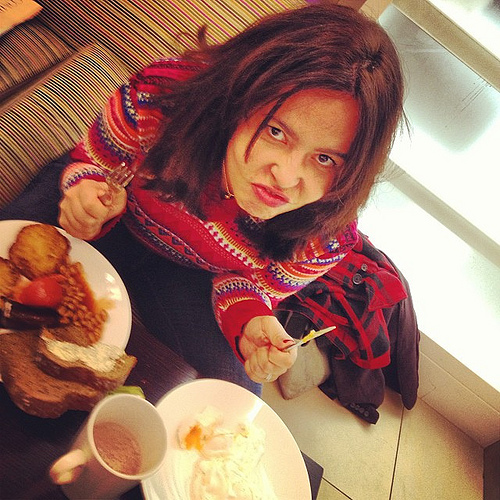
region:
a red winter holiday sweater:
[65, 49, 351, 362]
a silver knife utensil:
[282, 322, 333, 351]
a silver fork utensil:
[98, 160, 133, 206]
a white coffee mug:
[49, 391, 167, 493]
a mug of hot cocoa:
[49, 393, 166, 498]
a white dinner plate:
[139, 376, 309, 498]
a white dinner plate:
[1, 218, 130, 363]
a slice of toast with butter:
[35, 322, 132, 392]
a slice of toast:
[0, 330, 112, 415]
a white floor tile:
[385, 393, 483, 497]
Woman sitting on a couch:
[58, 5, 417, 397]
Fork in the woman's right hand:
[98, 161, 135, 207]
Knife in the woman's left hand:
[283, 325, 336, 352]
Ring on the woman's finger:
[263, 372, 275, 380]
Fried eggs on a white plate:
[178, 406, 278, 499]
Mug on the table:
[51, 392, 168, 499]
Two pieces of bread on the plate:
[3, 332, 136, 415]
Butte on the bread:
[46, 334, 125, 373]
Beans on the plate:
[57, 257, 109, 344]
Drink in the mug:
[94, 421, 141, 473]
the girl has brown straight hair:
[139, 2, 410, 265]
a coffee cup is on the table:
[41, 390, 168, 497]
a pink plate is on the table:
[139, 376, 313, 498]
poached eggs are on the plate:
[176, 408, 258, 498]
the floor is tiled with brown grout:
[263, 338, 494, 498]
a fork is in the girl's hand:
[55, 155, 132, 236]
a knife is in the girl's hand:
[235, 315, 335, 381]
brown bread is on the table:
[0, 329, 137, 415]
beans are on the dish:
[53, 259, 111, 342]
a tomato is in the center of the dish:
[20, 277, 63, 309]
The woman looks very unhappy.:
[121, 15, 399, 255]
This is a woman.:
[100, 12, 385, 232]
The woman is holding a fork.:
[58, 163, 170, 260]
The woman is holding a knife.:
[240, 290, 368, 385]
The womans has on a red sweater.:
[89, 85, 324, 319]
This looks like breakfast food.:
[9, 215, 131, 403]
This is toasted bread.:
[5, 332, 81, 417]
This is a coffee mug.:
[48, 395, 168, 497]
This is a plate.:
[150, 367, 313, 497]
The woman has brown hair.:
[229, 8, 410, 103]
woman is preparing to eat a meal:
[6, 5, 488, 499]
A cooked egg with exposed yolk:
[165, 407, 219, 453]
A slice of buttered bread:
[40, 325, 128, 385]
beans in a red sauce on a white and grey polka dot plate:
[58, 264, 100, 339]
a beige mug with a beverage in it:
[70, 399, 162, 494]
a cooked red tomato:
[18, 275, 68, 308]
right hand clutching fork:
[55, 156, 124, 236]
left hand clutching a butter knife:
[240, 302, 334, 392]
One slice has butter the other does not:
[0, 332, 127, 408]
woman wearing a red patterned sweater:
[72, 49, 395, 339]